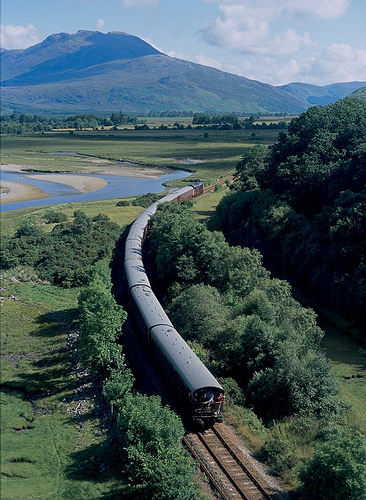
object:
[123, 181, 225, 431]
cars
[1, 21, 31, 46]
clouds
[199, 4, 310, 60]
clouds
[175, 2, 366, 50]
sky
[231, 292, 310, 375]
trees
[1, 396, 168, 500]
grass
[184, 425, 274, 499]
tracks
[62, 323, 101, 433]
gravel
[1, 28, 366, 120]
mountainside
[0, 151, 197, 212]
pond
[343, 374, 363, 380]
hole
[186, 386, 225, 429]
front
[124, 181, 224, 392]
top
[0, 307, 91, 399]
shadows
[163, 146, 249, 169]
shadows